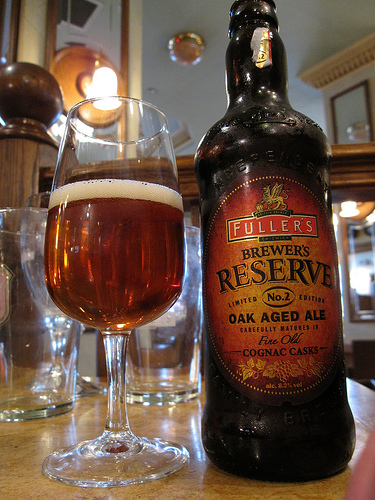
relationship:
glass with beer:
[38, 90, 198, 495] [38, 177, 193, 340]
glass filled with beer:
[38, 90, 198, 495] [38, 177, 193, 340]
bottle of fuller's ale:
[192, 2, 354, 484] [215, 212, 339, 358]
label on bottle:
[195, 156, 347, 405] [192, 2, 354, 484]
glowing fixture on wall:
[81, 60, 131, 112] [35, 11, 201, 141]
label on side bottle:
[195, 156, 347, 405] [192, 2, 354, 484]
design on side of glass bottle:
[247, 180, 298, 217] [192, 2, 354, 484]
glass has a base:
[38, 90, 198, 495] [34, 431, 198, 495]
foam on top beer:
[41, 177, 185, 209] [38, 177, 193, 340]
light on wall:
[81, 60, 131, 112] [35, 11, 201, 141]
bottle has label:
[192, 2, 354, 484] [195, 156, 347, 405]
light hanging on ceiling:
[81, 60, 131, 112] [8, 0, 223, 117]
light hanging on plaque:
[335, 192, 365, 224] [329, 195, 373, 231]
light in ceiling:
[81, 60, 131, 112] [8, 0, 223, 117]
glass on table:
[126, 217, 206, 413] [5, 395, 367, 499]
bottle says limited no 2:
[192, 2, 354, 484] [223, 281, 298, 311]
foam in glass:
[41, 177, 185, 209] [38, 90, 198, 495]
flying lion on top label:
[247, 180, 298, 217] [195, 156, 347, 405]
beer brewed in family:
[38, 177, 193, 340] [195, 156, 347, 405]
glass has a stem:
[38, 90, 198, 495] [100, 326, 133, 435]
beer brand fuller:
[192, 2, 354, 484] [223, 212, 320, 240]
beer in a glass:
[38, 177, 193, 340] [38, 90, 198, 495]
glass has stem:
[38, 90, 198, 495] [100, 326, 133, 435]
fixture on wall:
[164, 27, 212, 73] [35, 11, 201, 141]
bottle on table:
[192, 2, 354, 484] [5, 395, 367, 499]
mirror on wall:
[41, 2, 135, 164] [35, 11, 201, 141]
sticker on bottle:
[241, 25, 278, 70] [192, 2, 354, 484]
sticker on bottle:
[250, 27, 274, 69] [192, 2, 354, 484]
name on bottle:
[223, 212, 320, 240] [192, 2, 354, 484]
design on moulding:
[164, 27, 212, 73] [299, 30, 369, 89]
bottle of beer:
[192, 2, 354, 484] [192, 2, 354, 484]